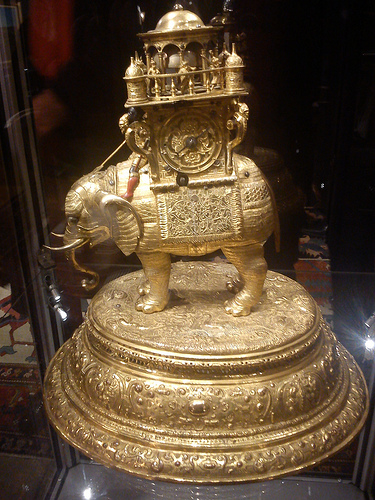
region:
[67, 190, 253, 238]
shiny metal made elephant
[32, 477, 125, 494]
shiny grey table surface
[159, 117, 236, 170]
brown antique wall clock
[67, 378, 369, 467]
shiny brown round bottom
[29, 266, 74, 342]
long shiny brown surface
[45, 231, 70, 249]
two grey elephant tusks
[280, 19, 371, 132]
dark black hidden surface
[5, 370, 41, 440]
flower colored floor mat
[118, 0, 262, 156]
tall beautiful city model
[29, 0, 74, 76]
red wide hanging object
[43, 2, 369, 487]
gold elephant statue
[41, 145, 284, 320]
gold elephant on gold statue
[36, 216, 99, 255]
two gold elephant tusks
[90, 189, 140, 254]
one gold elephant ear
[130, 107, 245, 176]
gold clock on statue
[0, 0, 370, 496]
clear glass display case for gold elephant statue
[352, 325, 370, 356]
white spotlight reflected in glass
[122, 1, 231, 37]
gold bell shaped dome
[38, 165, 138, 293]
gold elephant head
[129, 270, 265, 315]
gold elephant feet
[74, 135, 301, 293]
Gold elephant statue.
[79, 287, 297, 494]
Round gold base under elephant.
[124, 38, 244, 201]
Large gold decoration on top of elephant's back.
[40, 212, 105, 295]
Elephant has gold tusks.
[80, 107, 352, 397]
Gold elephant decoration is in glass case.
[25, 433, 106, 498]
Glass case near elephant decoration.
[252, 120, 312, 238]
Reflection of elephant off of glass case.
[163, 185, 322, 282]
Gold blanket over elephant's back.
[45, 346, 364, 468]
Large gold ornate elephant decoration.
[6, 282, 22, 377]
Area rug behind elephant.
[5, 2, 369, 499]
golden idol in a glass case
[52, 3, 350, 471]
golden elephant statue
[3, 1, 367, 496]
golden elephant statue in a museum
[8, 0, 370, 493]
golden Thai elephant statue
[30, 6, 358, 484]
golden thai elephant idol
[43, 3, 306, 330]
golden elephant carrying a box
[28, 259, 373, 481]
golden platform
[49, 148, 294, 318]
elephant statue made of gold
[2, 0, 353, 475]
elephant idol made of gold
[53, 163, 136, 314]
golden elephant head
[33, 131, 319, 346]
gold metal elephant statue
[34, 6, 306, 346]
decorative gold elephant statue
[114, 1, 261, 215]
golden metal statue of a building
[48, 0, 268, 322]
golden building on a golden elephant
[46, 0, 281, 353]
golden elephant with golden building on back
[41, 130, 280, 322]
decorative gold details on golden elephant statue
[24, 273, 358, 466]
golden pedastal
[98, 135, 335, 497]
golden elephant on golden pedastal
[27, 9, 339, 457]
golden statue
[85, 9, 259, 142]
golden building with windows